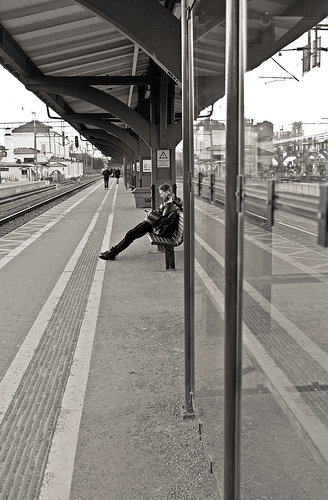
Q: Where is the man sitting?
A: On a bench.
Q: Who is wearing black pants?
A: Man on the bench.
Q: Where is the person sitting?
A: On a dark bench.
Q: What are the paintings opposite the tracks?
A: White lines.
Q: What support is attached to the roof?
A: Metal arches.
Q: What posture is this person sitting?
A: With all legs spread.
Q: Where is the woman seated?
A: At railway station.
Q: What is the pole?
A: A pillar.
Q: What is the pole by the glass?
A: A pillar.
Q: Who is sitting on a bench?
A: A person.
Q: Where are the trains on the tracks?
A: There are no trains.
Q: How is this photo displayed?
A: In black and white.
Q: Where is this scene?
A: Train station.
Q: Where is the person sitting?
A: On a bench.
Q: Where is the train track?
A: In front of the bench.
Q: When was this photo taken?
A: During the day.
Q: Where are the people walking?
A: On the platform.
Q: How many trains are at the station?
A: None.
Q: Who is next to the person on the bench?
A: No one.